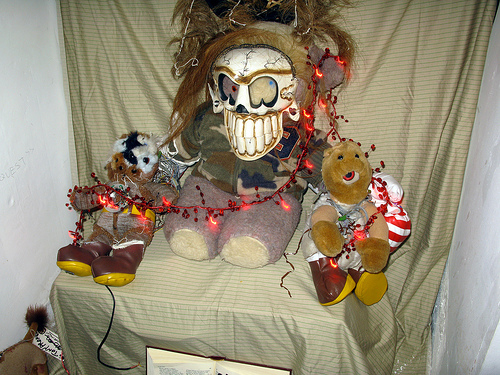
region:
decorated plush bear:
[300, 138, 395, 312]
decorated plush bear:
[54, 126, 177, 291]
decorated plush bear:
[161, 2, 333, 270]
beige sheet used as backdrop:
[61, 2, 497, 369]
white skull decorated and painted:
[199, 22, 306, 167]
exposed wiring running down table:
[78, 284, 144, 374]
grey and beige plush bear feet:
[162, 170, 303, 270]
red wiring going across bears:
[275, 43, 354, 206]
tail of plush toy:
[20, 302, 52, 344]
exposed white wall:
[427, 12, 495, 374]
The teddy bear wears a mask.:
[160, 6, 317, 268]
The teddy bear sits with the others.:
[304, 141, 389, 310]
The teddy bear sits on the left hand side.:
[57, 130, 176, 288]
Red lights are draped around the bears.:
[93, 173, 301, 220]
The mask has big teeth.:
[222, 113, 279, 155]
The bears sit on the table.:
[49, 184, 376, 374]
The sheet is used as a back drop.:
[376, 8, 459, 107]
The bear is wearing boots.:
[93, 241, 148, 285]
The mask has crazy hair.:
[171, 5, 321, 46]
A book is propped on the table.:
[137, 344, 301, 374]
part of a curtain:
[434, 255, 440, 265]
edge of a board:
[285, 299, 300, 321]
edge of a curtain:
[436, 258, 441, 270]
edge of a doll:
[344, 249, 353, 266]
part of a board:
[165, 343, 190, 368]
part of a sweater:
[361, 258, 378, 273]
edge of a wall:
[441, 345, 451, 356]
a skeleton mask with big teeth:
[209, 48, 296, 160]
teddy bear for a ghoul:
[54, 131, 175, 286]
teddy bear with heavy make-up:
[162, 0, 336, 266]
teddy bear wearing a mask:
[168, 0, 352, 270]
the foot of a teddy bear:
[219, 236, 270, 268]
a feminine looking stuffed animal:
[307, 141, 389, 305]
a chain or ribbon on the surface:
[278, 225, 315, 299]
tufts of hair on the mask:
[160, 59, 212, 149]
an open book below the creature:
[144, 346, 291, 373]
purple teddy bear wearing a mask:
[178, 21, 336, 260]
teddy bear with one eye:
[312, 143, 389, 305]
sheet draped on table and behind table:
[63, 8, 434, 373]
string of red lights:
[95, 63, 350, 231]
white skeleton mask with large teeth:
[205, 49, 300, 159]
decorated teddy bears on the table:
[64, 40, 408, 298]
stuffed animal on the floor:
[3, 301, 70, 373]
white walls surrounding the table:
[1, 3, 498, 373]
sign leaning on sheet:
[140, 346, 290, 374]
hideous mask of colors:
[209, 46, 282, 143]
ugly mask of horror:
[223, 118, 255, 150]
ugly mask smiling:
[216, 100, 272, 157]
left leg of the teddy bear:
[232, 196, 274, 257]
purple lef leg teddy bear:
[233, 200, 285, 262]